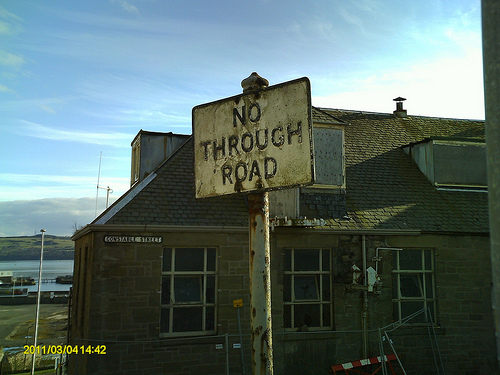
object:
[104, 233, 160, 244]
sign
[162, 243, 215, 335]
window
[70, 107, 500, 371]
house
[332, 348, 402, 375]
construction sign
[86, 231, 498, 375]
wall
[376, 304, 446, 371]
pipes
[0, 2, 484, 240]
sky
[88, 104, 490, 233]
roof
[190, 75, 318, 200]
sign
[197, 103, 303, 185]
no through road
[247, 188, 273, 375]
pole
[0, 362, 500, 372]
ground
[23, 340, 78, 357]
date stamp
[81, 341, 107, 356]
time stamp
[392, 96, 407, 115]
chimney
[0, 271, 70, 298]
shore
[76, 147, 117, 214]
antenna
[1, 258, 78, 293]
water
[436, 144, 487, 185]
window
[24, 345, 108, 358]
date and time stamp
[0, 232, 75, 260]
hill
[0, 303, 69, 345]
field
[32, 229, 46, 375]
pole